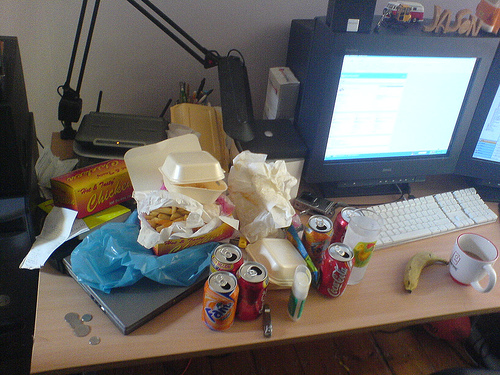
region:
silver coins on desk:
[41, 301, 118, 372]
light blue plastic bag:
[67, 230, 138, 299]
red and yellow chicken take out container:
[52, 161, 125, 219]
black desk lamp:
[63, 8, 255, 119]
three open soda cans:
[204, 239, 267, 334]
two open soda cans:
[300, 202, 360, 303]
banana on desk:
[390, 242, 454, 314]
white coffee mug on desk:
[438, 229, 498, 308]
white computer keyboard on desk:
[373, 192, 487, 247]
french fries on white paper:
[113, 197, 220, 249]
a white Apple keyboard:
[346, 184, 498, 249]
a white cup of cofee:
[446, 230, 498, 295]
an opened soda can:
[200, 272, 237, 332]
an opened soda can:
[210, 243, 240, 275]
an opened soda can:
[230, 260, 265, 320]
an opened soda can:
[318, 239, 349, 298]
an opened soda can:
[303, 215, 330, 250]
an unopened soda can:
[335, 208, 360, 243]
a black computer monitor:
[280, 16, 490, 197]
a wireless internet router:
[70, 88, 172, 160]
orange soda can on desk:
[176, 270, 247, 331]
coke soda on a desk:
[315, 235, 380, 295]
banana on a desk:
[395, 232, 452, 297]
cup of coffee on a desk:
[437, 220, 494, 296]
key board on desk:
[355, 180, 491, 240]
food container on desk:
[150, 146, 230, 202]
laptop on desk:
[96, 290, 173, 335]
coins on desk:
[50, 295, 105, 346]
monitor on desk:
[327, 55, 482, 181]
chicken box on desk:
[43, 152, 133, 208]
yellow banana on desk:
[400, 241, 450, 301]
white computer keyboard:
[396, 191, 493, 240]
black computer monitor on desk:
[305, 26, 490, 185]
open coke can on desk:
[319, 239, 361, 319]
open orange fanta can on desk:
[203, 271, 243, 333]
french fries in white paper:
[132, 196, 204, 246]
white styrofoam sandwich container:
[154, 148, 231, 207]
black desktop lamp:
[52, 13, 256, 100]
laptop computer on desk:
[95, 290, 186, 343]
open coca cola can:
[321, 242, 353, 299]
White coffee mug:
[447, 232, 497, 295]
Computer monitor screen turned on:
[307, 28, 481, 180]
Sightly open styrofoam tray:
[159, 151, 225, 202]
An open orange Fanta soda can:
[205, 270, 237, 330]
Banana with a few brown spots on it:
[403, 247, 450, 292]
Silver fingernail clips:
[261, 302, 274, 339]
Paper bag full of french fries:
[138, 196, 207, 236]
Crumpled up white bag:
[227, 153, 292, 234]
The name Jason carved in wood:
[421, 5, 483, 37]